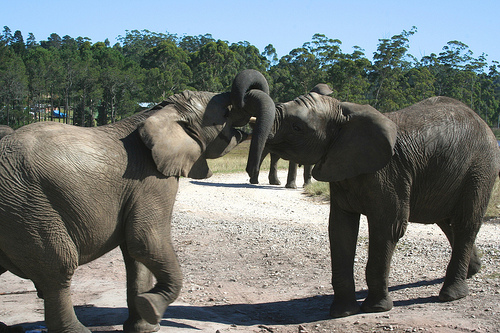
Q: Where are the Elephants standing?
A: A gravel road.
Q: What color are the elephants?
A: Gray.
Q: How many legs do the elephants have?
A: Four.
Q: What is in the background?
A: Trees.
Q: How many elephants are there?
A: Three.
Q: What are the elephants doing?
A: Twisting trunks.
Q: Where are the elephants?
A: At the zoo.